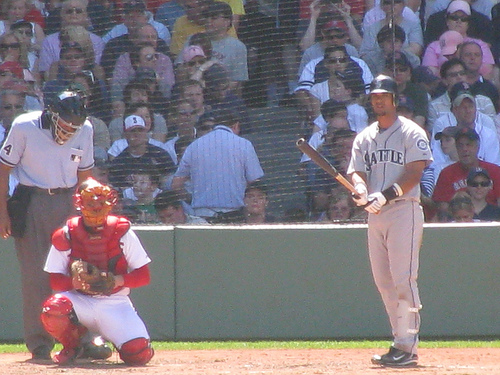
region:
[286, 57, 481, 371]
a man with a baseball bat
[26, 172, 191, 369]
the catcher is wearing red and white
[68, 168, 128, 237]
the catcher is wearing a face mask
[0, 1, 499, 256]
people watching the game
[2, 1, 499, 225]
a net between the players and the watchers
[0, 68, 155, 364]
the umpire is looking down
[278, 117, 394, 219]
the bat is brown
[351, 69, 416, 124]
the batter's helmet is black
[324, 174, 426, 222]
the batter's gloves are black and white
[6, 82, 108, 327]
the umpire is wearing a belt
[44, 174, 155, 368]
a man in a red and white uniform.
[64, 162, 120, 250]
a face guard on a person.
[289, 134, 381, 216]
a person holding a baseball bat.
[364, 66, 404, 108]
a blue hat on a person.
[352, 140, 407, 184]
writing on a shirt.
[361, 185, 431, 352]
a pair of baseball pants.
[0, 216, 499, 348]
a green wall in front of a crowd.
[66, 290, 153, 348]
a pair of white shorts.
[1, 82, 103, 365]
an umpire standing behind a catcher.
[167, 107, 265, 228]
a man walking up stairs.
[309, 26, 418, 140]
the helmet is black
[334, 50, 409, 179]
the helmet is black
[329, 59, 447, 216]
the helmet is black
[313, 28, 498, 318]
the helmet is black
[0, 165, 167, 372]
catcher wearing red and white kneeling down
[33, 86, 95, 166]
Umpire wearing black helmet with white face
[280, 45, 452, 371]
player wearing grey holding bat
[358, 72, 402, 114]
black helmet on batter's head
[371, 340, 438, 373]
black nike brand cleats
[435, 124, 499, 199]
old man wearing red tee shirt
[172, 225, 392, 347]
low grey wall behind players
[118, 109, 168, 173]
man in crowd wearing white hat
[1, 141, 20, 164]
black A on umpires sleeve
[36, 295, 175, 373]
bright red knee pads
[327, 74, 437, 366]
Man wearing gray uniform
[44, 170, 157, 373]
Man wearing red protective gear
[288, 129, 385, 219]
Bat in man's hand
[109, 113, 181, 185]
Man wearing red and white cap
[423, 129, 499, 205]
Man wearing red shirt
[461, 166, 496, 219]
Woman wearing black sunglasses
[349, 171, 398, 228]
White gloves on man's hands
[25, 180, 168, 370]
Man kneeling in dirt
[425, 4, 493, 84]
Woman in pink hat and shirt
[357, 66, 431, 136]
Black helmet on man's head